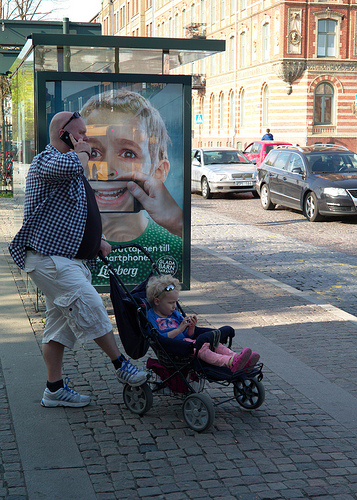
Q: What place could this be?
A: It is a sidewalk.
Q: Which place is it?
A: It is a sidewalk.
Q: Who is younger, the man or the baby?
A: The baby is younger than the man.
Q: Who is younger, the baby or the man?
A: The baby is younger than the man.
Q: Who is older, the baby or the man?
A: The man is older than the baby.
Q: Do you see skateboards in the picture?
A: No, there are no skateboards.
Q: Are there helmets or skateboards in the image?
A: No, there are no skateboards or helmets.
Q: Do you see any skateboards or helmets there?
A: No, there are no skateboards or helmets.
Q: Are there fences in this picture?
A: No, there are no fences.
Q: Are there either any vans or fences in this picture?
A: No, there are no fences or vans.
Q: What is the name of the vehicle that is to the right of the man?
A: The vehicle is a car.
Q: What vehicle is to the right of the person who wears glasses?
A: The vehicle is a car.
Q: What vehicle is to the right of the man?
A: The vehicle is a car.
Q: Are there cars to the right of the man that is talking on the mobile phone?
A: Yes, there is a car to the right of the man.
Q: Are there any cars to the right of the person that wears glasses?
A: Yes, there is a car to the right of the man.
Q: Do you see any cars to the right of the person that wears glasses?
A: Yes, there is a car to the right of the man.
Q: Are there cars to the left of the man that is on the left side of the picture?
A: No, the car is to the right of the man.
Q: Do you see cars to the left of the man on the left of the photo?
A: No, the car is to the right of the man.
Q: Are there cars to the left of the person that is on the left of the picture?
A: No, the car is to the right of the man.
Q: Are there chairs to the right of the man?
A: No, there is a car to the right of the man.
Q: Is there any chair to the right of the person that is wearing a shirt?
A: No, there is a car to the right of the man.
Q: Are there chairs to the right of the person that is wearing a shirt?
A: No, there is a car to the right of the man.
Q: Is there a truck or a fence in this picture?
A: No, there are no fences or trucks.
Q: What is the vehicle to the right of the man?
A: The vehicle is a car.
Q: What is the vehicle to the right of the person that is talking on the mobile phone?
A: The vehicle is a car.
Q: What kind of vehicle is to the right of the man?
A: The vehicle is a car.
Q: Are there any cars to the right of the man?
A: Yes, there is a car to the right of the man.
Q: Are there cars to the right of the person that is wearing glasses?
A: Yes, there is a car to the right of the man.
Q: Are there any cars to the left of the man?
A: No, the car is to the right of the man.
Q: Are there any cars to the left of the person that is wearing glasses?
A: No, the car is to the right of the man.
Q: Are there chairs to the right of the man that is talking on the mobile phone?
A: No, there is a car to the right of the man.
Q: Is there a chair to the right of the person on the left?
A: No, there is a car to the right of the man.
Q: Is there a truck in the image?
A: No, there are no trucks.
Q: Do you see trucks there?
A: No, there are no trucks.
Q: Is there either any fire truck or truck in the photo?
A: No, there are no trucks or fire trucks.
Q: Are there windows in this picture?
A: Yes, there is a window.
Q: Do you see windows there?
A: Yes, there is a window.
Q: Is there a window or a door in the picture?
A: Yes, there is a window.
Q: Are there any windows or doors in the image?
A: Yes, there is a window.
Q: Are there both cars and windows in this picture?
A: Yes, there are both a window and a car.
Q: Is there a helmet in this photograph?
A: No, there are no helmets.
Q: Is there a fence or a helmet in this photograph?
A: No, there are no helmets or fences.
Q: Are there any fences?
A: No, there are no fences.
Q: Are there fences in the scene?
A: No, there are no fences.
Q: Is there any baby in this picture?
A: Yes, there is a baby.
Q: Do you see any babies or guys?
A: Yes, there is a baby.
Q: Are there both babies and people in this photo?
A: Yes, there are both a baby and a person.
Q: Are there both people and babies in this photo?
A: Yes, there are both a baby and a person.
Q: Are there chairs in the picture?
A: No, there are no chairs.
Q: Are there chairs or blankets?
A: No, there are no chairs or blankets.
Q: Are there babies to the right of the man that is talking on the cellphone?
A: Yes, there is a baby to the right of the man.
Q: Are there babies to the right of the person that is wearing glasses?
A: Yes, there is a baby to the right of the man.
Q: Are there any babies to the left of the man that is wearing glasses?
A: No, the baby is to the right of the man.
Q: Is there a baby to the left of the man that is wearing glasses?
A: No, the baby is to the right of the man.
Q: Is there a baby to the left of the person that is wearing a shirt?
A: No, the baby is to the right of the man.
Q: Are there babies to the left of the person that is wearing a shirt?
A: No, the baby is to the right of the man.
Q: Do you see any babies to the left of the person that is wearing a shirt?
A: No, the baby is to the right of the man.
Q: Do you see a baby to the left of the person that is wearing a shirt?
A: No, the baby is to the right of the man.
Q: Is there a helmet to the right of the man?
A: No, there is a baby to the right of the man.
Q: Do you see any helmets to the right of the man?
A: No, there is a baby to the right of the man.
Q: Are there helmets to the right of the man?
A: No, there is a baby to the right of the man.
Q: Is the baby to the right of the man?
A: Yes, the baby is to the right of the man.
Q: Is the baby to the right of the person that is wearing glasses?
A: Yes, the baby is to the right of the man.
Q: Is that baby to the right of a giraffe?
A: No, the baby is to the right of the man.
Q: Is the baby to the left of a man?
A: No, the baby is to the right of a man.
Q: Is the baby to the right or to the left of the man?
A: The baby is to the right of the man.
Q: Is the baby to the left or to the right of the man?
A: The baby is to the right of the man.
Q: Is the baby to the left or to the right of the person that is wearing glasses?
A: The baby is to the right of the man.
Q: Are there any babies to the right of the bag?
A: Yes, there is a baby to the right of the bag.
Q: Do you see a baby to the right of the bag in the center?
A: Yes, there is a baby to the right of the bag.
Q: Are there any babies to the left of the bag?
A: No, the baby is to the right of the bag.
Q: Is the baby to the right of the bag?
A: Yes, the baby is to the right of the bag.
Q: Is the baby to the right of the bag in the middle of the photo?
A: Yes, the baby is to the right of the bag.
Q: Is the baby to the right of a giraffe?
A: No, the baby is to the right of the bag.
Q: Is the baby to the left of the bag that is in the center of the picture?
A: No, the baby is to the right of the bag.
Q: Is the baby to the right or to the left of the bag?
A: The baby is to the right of the bag.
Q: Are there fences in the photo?
A: No, there are no fences.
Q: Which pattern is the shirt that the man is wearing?
A: The shirt is checkered.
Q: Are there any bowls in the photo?
A: No, there are no bowls.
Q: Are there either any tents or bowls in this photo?
A: No, there are no bowls or tents.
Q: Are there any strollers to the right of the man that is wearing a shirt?
A: Yes, there is a stroller to the right of the man.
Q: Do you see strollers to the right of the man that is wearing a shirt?
A: Yes, there is a stroller to the right of the man.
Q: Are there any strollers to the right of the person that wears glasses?
A: Yes, there is a stroller to the right of the man.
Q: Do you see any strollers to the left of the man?
A: No, the stroller is to the right of the man.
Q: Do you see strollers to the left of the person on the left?
A: No, the stroller is to the right of the man.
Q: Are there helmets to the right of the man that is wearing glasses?
A: No, there is a stroller to the right of the man.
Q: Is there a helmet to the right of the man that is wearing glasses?
A: No, there is a stroller to the right of the man.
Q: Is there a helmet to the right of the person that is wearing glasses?
A: No, there is a stroller to the right of the man.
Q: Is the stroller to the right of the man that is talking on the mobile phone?
A: Yes, the stroller is to the right of the man.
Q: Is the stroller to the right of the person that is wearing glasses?
A: Yes, the stroller is to the right of the man.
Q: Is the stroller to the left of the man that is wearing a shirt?
A: No, the stroller is to the right of the man.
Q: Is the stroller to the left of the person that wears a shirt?
A: No, the stroller is to the right of the man.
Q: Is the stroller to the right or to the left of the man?
A: The stroller is to the right of the man.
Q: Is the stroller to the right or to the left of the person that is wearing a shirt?
A: The stroller is to the right of the man.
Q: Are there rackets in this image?
A: No, there are no rackets.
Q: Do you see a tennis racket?
A: No, there are no rackets.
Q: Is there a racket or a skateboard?
A: No, there are no rackets or skateboards.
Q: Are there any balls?
A: No, there are no balls.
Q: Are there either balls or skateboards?
A: No, there are no balls or skateboards.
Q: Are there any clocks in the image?
A: No, there are no clocks.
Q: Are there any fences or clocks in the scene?
A: No, there are no clocks or fences.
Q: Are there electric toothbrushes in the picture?
A: No, there are no electric toothbrushes.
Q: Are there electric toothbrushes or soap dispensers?
A: No, there are no electric toothbrushes or soap dispensers.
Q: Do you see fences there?
A: No, there are no fences.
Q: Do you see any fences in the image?
A: No, there are no fences.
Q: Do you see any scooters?
A: No, there are no scooters.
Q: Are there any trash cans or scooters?
A: No, there are no scooters or trash cans.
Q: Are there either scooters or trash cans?
A: No, there are no scooters or trash cans.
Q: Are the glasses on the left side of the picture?
A: Yes, the glasses are on the left of the image.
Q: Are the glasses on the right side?
A: No, the glasses are on the left of the image.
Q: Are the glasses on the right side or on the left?
A: The glasses are on the left of the image.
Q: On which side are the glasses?
A: The glasses are on the left of the image.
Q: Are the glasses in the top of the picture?
A: Yes, the glasses are in the top of the image.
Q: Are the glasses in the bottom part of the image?
A: No, the glasses are in the top of the image.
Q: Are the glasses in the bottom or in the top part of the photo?
A: The glasses are in the top of the image.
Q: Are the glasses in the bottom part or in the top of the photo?
A: The glasses are in the top of the image.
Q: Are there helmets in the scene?
A: No, there are no helmets.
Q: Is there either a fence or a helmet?
A: No, there are no helmets or fences.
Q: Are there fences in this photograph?
A: No, there are no fences.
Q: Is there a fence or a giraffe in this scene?
A: No, there are no fences or giraffes.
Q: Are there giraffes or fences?
A: No, there are no fences or giraffes.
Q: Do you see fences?
A: No, there are no fences.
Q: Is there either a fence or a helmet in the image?
A: No, there are no fences or helmets.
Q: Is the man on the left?
A: Yes, the man is on the left of the image.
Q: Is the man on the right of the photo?
A: No, the man is on the left of the image.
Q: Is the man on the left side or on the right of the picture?
A: The man is on the left of the image.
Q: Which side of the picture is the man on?
A: The man is on the left of the image.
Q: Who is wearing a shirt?
A: The man is wearing a shirt.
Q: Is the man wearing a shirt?
A: Yes, the man is wearing a shirt.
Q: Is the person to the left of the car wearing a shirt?
A: Yes, the man is wearing a shirt.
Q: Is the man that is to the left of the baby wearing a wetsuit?
A: No, the man is wearing a shirt.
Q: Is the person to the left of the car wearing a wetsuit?
A: No, the man is wearing a shirt.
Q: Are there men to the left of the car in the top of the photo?
A: Yes, there is a man to the left of the car.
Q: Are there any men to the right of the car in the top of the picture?
A: No, the man is to the left of the car.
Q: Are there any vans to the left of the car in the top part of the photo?
A: No, there is a man to the left of the car.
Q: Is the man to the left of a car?
A: Yes, the man is to the left of a car.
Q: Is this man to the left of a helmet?
A: No, the man is to the left of a car.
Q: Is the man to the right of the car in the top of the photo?
A: No, the man is to the left of the car.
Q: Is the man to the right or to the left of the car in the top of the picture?
A: The man is to the left of the car.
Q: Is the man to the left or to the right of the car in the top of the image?
A: The man is to the left of the car.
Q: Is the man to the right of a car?
A: No, the man is to the left of a car.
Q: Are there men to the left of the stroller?
A: Yes, there is a man to the left of the stroller.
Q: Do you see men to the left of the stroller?
A: Yes, there is a man to the left of the stroller.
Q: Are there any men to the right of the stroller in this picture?
A: No, the man is to the left of the stroller.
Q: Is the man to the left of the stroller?
A: Yes, the man is to the left of the stroller.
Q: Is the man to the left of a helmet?
A: No, the man is to the left of the stroller.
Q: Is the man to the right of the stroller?
A: No, the man is to the left of the stroller.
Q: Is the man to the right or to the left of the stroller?
A: The man is to the left of the stroller.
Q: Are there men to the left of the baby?
A: Yes, there is a man to the left of the baby.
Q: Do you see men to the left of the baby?
A: Yes, there is a man to the left of the baby.